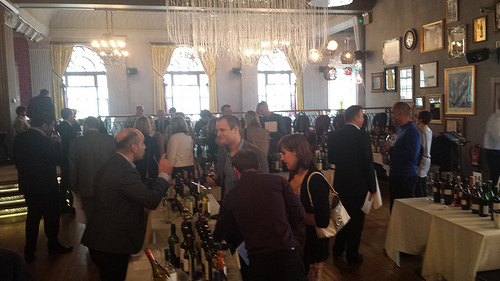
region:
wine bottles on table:
[412, 165, 486, 227]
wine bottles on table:
[401, 175, 478, 251]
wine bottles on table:
[152, 240, 232, 275]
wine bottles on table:
[164, 212, 225, 273]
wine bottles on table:
[137, 230, 202, 272]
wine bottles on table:
[148, 201, 196, 253]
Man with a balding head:
[82, 120, 174, 275]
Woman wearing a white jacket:
[162, 107, 197, 194]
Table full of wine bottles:
[130, 168, 230, 280]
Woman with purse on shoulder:
[268, 131, 351, 278]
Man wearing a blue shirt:
[382, 103, 427, 201]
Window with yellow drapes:
[140, 37, 235, 122]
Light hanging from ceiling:
[81, 6, 141, 68]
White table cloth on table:
[383, 196, 495, 278]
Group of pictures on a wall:
[368, 0, 494, 132]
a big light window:
[51, 42, 113, 126]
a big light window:
[153, 47, 216, 114]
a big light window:
[251, 43, 298, 118]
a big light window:
[326, 42, 366, 110]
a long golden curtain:
[51, 37, 81, 119]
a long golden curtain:
[150, 41, 175, 115]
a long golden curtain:
[197, 46, 223, 110]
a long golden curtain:
[282, 43, 307, 114]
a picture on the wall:
[402, 28, 414, 46]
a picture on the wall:
[442, 66, 473, 113]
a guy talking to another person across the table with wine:
[86, 100, 245, 273]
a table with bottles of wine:
[411, 163, 496, 273]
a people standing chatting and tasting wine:
[11, 86, 436, 268]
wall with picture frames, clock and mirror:
[371, 7, 499, 107]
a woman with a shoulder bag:
[271, 126, 355, 279]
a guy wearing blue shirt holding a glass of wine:
[378, 91, 426, 243]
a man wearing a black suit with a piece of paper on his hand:
[327, 101, 380, 275]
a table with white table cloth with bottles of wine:
[386, 167, 497, 278]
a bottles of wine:
[157, 207, 226, 279]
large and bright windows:
[46, 42, 351, 106]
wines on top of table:
[404, 161, 494, 221]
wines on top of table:
[408, 160, 452, 195]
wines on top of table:
[395, 161, 485, 278]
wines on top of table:
[414, 177, 468, 225]